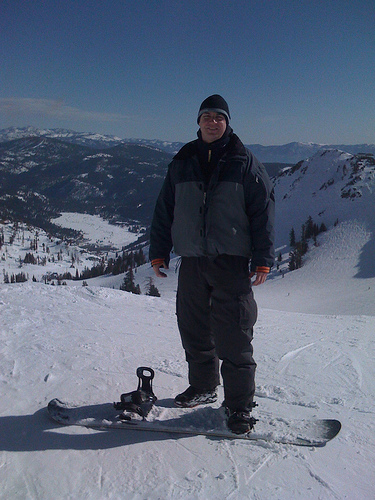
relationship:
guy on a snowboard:
[149, 90, 275, 439] [44, 383, 342, 453]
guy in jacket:
[149, 90, 275, 439] [175, 258, 257, 410]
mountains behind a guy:
[10, 126, 362, 231] [149, 90, 274, 432]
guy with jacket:
[149, 90, 275, 439] [175, 258, 257, 410]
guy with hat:
[149, 90, 275, 439] [194, 94, 230, 120]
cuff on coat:
[238, 248, 304, 295] [151, 133, 288, 293]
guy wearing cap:
[149, 90, 275, 439] [195, 95, 233, 124]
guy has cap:
[149, 90, 275, 439] [195, 84, 252, 146]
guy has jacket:
[149, 90, 275, 439] [175, 258, 257, 410]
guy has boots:
[149, 90, 275, 439] [169, 358, 282, 443]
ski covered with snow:
[49, 354, 360, 476] [249, 409, 305, 455]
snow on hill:
[271, 323, 367, 410] [17, 260, 337, 493]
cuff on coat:
[246, 251, 274, 276] [149, 128, 295, 269]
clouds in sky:
[7, 79, 139, 138] [36, 19, 127, 119]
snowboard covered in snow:
[36, 362, 357, 464] [263, 405, 297, 460]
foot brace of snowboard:
[98, 345, 193, 424] [21, 362, 357, 489]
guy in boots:
[149, 90, 275, 439] [178, 318, 316, 464]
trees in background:
[49, 224, 130, 297] [21, 150, 175, 330]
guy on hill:
[149, 90, 275, 439] [52, 261, 352, 468]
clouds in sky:
[0, 72, 375, 144] [113, 25, 258, 99]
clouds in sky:
[0, 72, 375, 144] [129, 23, 289, 100]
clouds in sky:
[0, 72, 375, 144] [51, 87, 179, 132]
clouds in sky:
[0, 72, 375, 144] [97, 17, 288, 100]